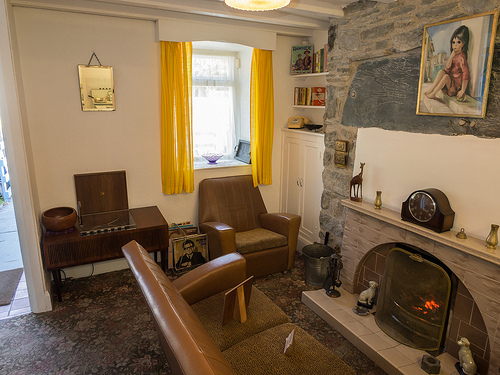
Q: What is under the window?
A: Chair.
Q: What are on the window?
A: Curtains.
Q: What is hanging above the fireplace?
A: Picture.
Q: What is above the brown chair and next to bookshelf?
A: Orange curtains near the window.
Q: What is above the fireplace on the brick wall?
A: Picture frame of kid.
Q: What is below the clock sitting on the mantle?
A: Fireplace in use.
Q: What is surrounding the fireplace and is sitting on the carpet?
A: Matching brown couch and armchair.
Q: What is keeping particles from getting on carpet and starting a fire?
A: Metal screen in front of fireplace.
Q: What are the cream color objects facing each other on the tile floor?
A: Two small ceramic dogs on either side of fireplace.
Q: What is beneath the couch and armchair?
A: Dark floral print carpet.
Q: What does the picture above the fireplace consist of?
A: Painting of a young girl sitting near a wall.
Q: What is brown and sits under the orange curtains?
A: Chair sitting under the window.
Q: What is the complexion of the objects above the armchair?
A: Bright yellow curtains on the window.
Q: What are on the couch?
A: Two picture frames.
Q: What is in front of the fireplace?
A: A brown couch.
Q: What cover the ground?
A: Carpet.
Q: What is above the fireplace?
A: A large painting with gold frame.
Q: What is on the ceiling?
A: A fancy light.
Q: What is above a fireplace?
A: A mantle.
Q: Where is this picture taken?
A: A living room.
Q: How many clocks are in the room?
A: One.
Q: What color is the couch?
A: Brown.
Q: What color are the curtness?
A: Yellow.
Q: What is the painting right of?
A: A little girl.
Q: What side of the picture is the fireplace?
A: Right.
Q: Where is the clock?
A: On mantle.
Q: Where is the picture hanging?
A: Above fireplace.